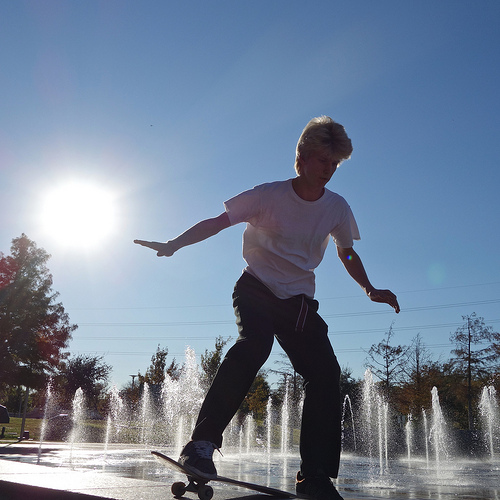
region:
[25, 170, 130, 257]
Bright sun in the sky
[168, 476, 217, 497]
Two wheels of a skateboard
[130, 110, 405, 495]
A woman is skateboarding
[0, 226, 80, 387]
Green leaves on a tree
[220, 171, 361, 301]
A white short sleeved shirt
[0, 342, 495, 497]
Water springing out of a fountain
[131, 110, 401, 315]
Woman has two arms raised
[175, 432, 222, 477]
Sneaker with white laces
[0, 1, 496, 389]
A bright blue sky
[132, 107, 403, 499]
person on a skateboard near water fouontains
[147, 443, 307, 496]
skateboard the person is riding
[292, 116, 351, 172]
blonde hair of the person on the skateboard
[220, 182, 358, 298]
white t-shirt the person is wearing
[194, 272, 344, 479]
dark-colored pants the person is wearing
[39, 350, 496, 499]
fountains spraying water in the air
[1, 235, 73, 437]
tree with red and green leaves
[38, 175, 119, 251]
sun shining brightly in the sky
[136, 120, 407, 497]
person doing a skateboard trick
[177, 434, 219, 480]
black shoe with white laces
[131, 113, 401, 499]
a person wearing a white t-shirt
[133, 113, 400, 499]
a blond haired person on a skateboard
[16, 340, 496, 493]
water spray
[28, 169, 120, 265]
the sun in the sky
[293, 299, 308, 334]
the belt piece that is hanging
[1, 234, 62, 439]
the tree with red leaves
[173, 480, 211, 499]
the skateboard wheels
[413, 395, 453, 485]
water streams coming from the ground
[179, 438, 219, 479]
the man's grey shoe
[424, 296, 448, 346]
power lines suspended in the air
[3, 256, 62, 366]
green leaves on the tree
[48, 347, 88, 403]
green leaves on the tree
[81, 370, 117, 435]
green leaves on the tree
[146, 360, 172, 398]
green leaves on the tree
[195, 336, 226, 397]
green leaves on the tree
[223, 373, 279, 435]
green leaves on the tree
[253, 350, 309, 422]
green leaves on the tree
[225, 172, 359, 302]
white shirt skater is wearing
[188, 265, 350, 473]
pants the skater is wearing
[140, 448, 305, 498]
skateboard the skater is using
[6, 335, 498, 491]
water feature behind the skater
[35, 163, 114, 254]
bright sun in the sky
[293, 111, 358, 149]
blonde hair of the skater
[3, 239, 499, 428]
trees behind the skater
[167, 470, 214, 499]
wheels on the skateboard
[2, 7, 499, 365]
clear blue sky behind the skater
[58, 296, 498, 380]
power lines behind the skater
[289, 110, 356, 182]
a young man with blonde hair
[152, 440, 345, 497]
a young man riding a skateboard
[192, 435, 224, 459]
white shoe laces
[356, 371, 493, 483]
several water fountains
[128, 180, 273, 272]
a young man with his arm stretched out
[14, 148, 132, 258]
the sun in the sky